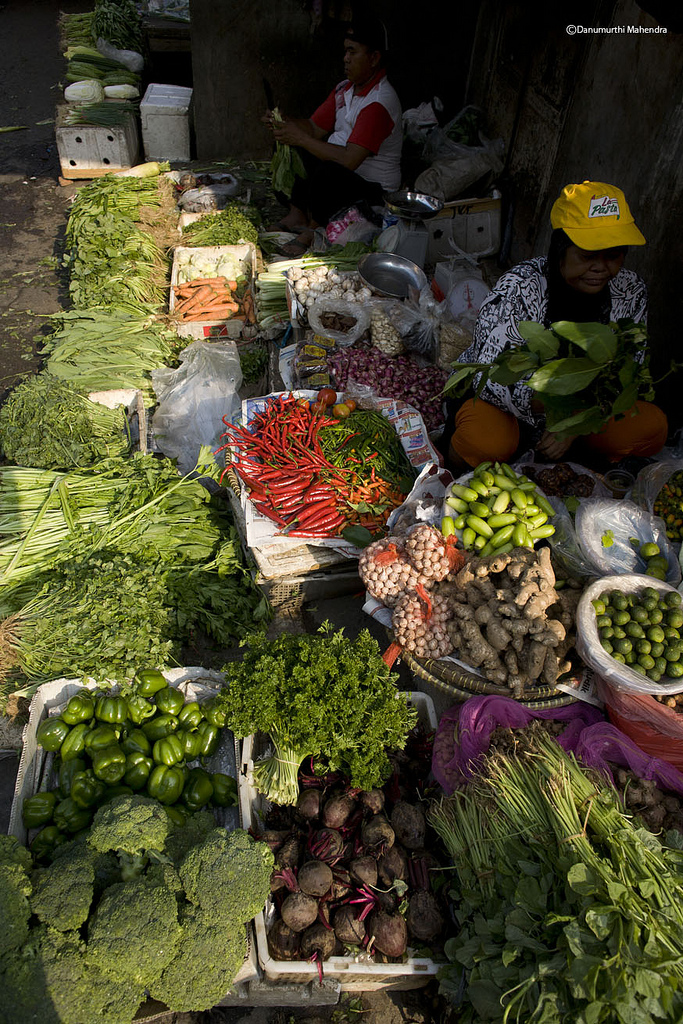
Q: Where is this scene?
A: At a farmer's market.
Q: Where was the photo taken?
A: An outdoor market.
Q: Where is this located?
A: In a garden.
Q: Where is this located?
A: At a market.